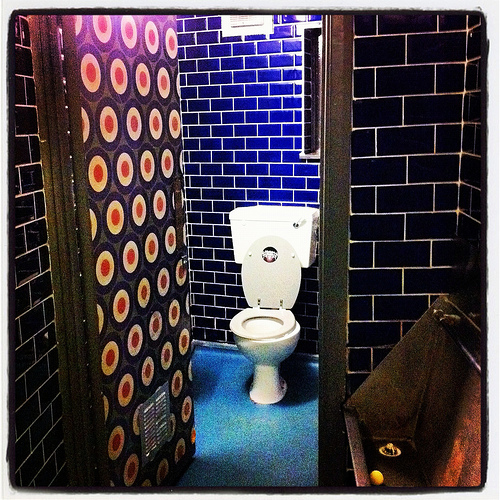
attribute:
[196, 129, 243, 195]
tile — blue 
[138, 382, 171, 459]
vent — metal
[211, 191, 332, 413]
toilet — bowl, white ceramic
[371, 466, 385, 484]
ball — yellow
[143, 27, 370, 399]
wall —  tiled blue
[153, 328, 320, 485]
floor — blue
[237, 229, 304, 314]
lid — white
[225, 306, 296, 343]
toilet-seat lid — crooked toilet seat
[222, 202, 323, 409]
toilet — white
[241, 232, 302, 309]
lid — toilet seat 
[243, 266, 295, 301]
toilet lid — toilet 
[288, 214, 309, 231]
flusher — Silver 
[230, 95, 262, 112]
tile — blue 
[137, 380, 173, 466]
vent — silver 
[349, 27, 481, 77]
tiles — Dark 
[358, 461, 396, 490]
ball — yellow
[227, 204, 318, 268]
tank — white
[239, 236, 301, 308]
toilet seat — toilet 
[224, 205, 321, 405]
urinal — men's 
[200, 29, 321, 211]
tiles — Blue 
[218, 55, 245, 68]
brick — blue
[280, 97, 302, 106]
brick — blue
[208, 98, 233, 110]
brick — blue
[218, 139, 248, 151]
brick — blue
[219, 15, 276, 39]
white — high 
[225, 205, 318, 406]
white toilet — white 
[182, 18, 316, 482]
restroom — public 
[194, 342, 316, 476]
floor — blue colored